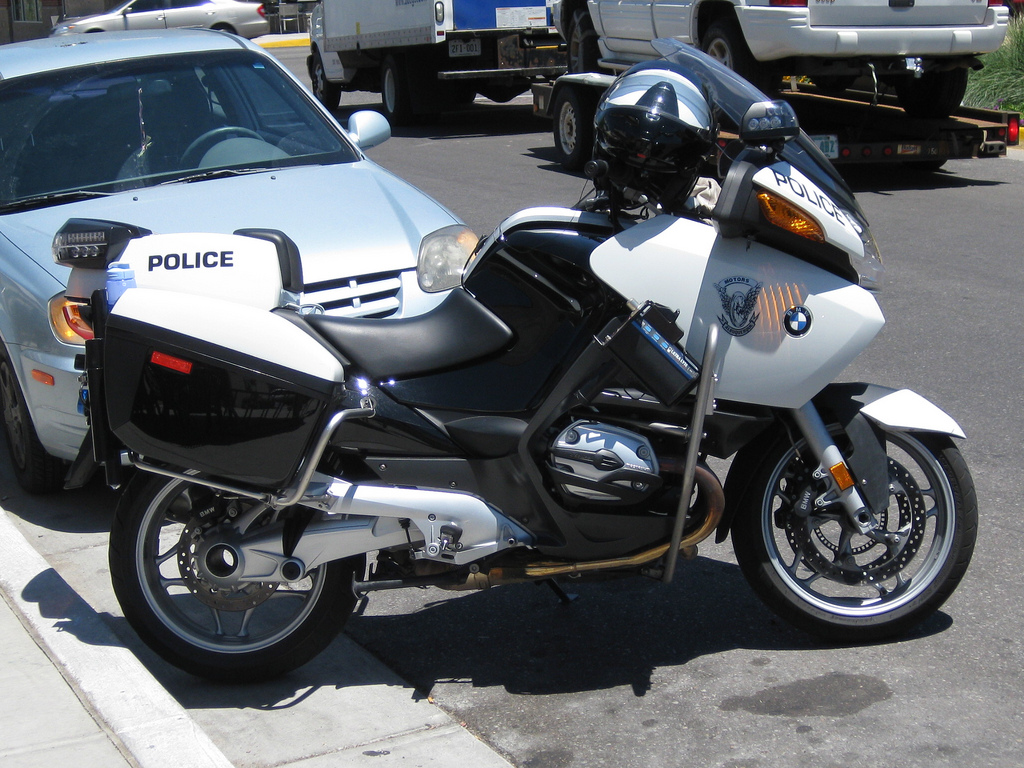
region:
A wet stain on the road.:
[717, 668, 891, 720]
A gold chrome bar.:
[527, 458, 724, 577]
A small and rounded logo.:
[781, 303, 814, 338]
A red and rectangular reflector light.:
[148, 350, 196, 377]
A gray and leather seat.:
[305, 291, 512, 381]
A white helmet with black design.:
[594, 67, 712, 148]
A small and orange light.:
[29, 369, 53, 386]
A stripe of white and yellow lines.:
[252, 31, 313, 50]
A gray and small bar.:
[657, 316, 721, 583]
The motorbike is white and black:
[51, 37, 976, 687]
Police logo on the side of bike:
[712, 264, 761, 334]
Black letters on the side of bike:
[141, 241, 233, 268]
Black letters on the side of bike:
[757, 160, 843, 222]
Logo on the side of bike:
[776, 296, 816, 341]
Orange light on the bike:
[747, 184, 828, 246]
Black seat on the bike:
[298, 279, 513, 403]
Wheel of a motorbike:
[724, 382, 981, 640]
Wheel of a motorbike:
[106, 468, 364, 688]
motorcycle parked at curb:
[42, 39, 997, 685]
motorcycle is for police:
[35, 28, 1001, 696]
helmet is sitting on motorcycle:
[570, 53, 717, 241]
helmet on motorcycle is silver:
[578, 53, 724, 219]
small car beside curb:
[3, 20, 509, 505]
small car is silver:
[0, 12, 498, 516]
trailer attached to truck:
[518, 46, 1022, 209]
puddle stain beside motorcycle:
[711, 662, 901, 736]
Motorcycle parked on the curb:
[19, 29, 974, 641]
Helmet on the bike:
[575, 53, 721, 193]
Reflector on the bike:
[822, 454, 855, 489]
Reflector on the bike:
[758, 187, 826, 236]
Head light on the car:
[419, 222, 486, 300]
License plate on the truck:
[439, 26, 487, 61]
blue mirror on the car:
[340, 94, 399, 161]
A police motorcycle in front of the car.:
[51, 202, 880, 642]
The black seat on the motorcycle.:
[328, 298, 499, 359]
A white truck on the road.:
[293, 7, 559, 112]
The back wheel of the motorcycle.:
[97, 470, 328, 673]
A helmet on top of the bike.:
[581, 42, 718, 194]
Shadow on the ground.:
[338, 570, 788, 682]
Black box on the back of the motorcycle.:
[35, 214, 146, 288]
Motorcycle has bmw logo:
[49, 31, 983, 687]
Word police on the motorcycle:
[142, 247, 240, 274]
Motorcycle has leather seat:
[43, 32, 983, 687]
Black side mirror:
[735, 94, 805, 164]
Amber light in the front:
[754, 190, 828, 249]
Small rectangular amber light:
[827, 458, 859, 497]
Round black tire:
[106, 456, 372, 687]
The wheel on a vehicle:
[104, 456, 358, 684]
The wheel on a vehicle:
[737, 376, 976, 642]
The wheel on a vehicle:
[891, 53, 971, 117]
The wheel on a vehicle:
[695, 23, 762, 94]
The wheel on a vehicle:
[4, 357, 39, 491]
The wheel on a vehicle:
[379, 51, 421, 132]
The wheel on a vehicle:
[310, 51, 337, 103]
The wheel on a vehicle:
[562, 13, 592, 71]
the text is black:
[149, 251, 242, 275]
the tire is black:
[731, 407, 979, 645]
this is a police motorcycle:
[194, 88, 929, 658]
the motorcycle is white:
[84, 136, 844, 551]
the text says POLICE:
[97, 190, 288, 361]